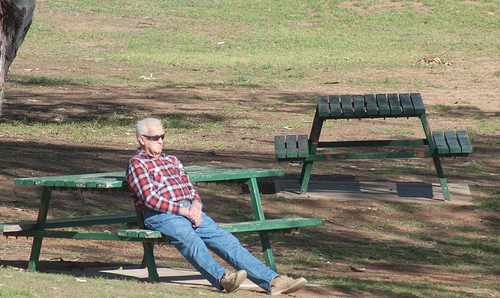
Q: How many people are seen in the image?
A: One.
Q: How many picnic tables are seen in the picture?
A: Two.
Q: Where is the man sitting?
A: At a picnic table.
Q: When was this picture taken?
A: During the day.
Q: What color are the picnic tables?
A: Green.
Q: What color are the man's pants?
A: Blue.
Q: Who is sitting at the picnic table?
A: An old man.